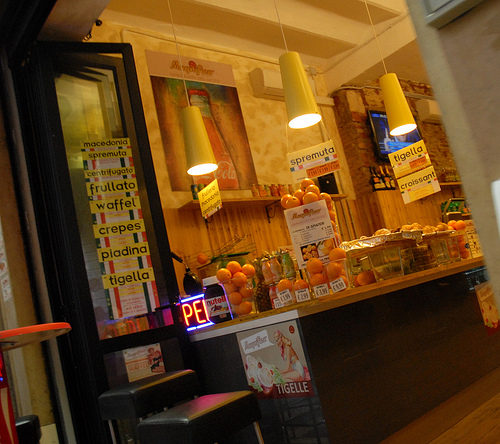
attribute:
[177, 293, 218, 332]
light up neon sign — blue, yellow